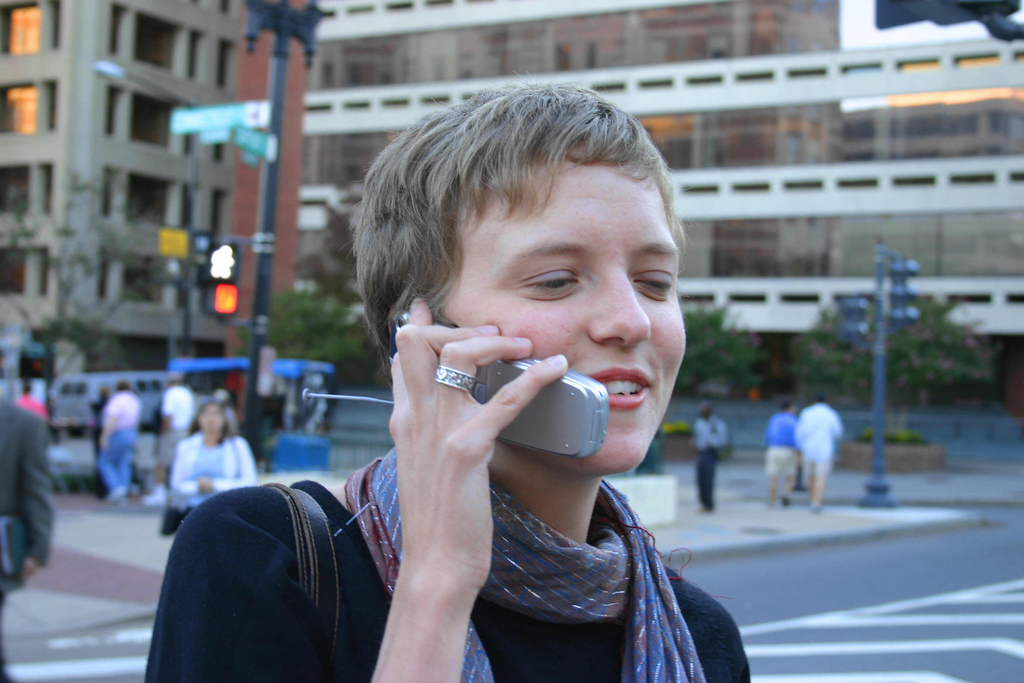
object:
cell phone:
[386, 315, 621, 463]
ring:
[427, 355, 474, 394]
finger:
[449, 350, 572, 463]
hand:
[375, 296, 572, 572]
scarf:
[343, 439, 708, 683]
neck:
[487, 439, 612, 556]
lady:
[129, 73, 750, 683]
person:
[762, 394, 809, 518]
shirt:
[764, 411, 808, 448]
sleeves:
[135, 482, 332, 683]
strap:
[257, 477, 359, 660]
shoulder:
[143, 470, 370, 589]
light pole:
[241, 19, 300, 448]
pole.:
[862, 233, 893, 509]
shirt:
[692, 417, 736, 454]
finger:
[433, 329, 529, 410]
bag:
[258, 470, 389, 678]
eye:
[508, 265, 581, 302]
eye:
[628, 261, 688, 305]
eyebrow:
[496, 235, 592, 268]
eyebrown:
[624, 231, 682, 271]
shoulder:
[657, 555, 772, 674]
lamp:
[830, 246, 926, 511]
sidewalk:
[681, 462, 1022, 494]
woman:
[154, 388, 261, 510]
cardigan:
[162, 432, 266, 505]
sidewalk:
[0, 441, 380, 632]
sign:
[198, 235, 250, 279]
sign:
[225, 116, 283, 164]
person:
[793, 394, 849, 511]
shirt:
[794, 403, 847, 464]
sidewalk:
[649, 500, 974, 556]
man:
[684, 397, 737, 518]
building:
[0, 0, 247, 410]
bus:
[52, 370, 177, 431]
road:
[0, 514, 1024, 683]